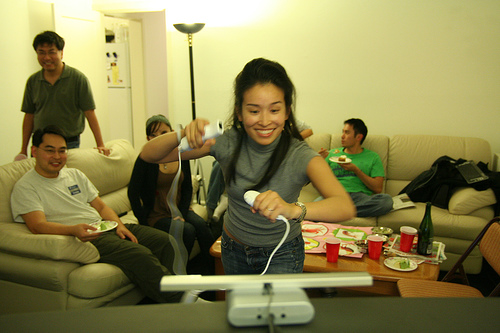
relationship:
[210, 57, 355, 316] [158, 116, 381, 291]
girl playing wii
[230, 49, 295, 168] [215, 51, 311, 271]
hair on girl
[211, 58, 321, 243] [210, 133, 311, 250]
woman wearing shirt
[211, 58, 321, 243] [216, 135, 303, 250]
woman wearing shirt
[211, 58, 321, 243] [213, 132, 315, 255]
woman wearing shirt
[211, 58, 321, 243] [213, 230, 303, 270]
woman wearing pants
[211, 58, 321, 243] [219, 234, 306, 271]
woman wearing pants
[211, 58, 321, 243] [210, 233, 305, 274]
woman wearing jeans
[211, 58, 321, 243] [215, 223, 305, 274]
woman wearing jeans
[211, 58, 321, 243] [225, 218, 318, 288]
woman wearing jeans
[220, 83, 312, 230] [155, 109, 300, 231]
woman holding remotes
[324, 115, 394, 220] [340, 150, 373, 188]
man wearing shirt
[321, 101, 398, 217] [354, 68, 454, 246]
man on couch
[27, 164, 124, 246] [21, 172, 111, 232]
man wearing shirt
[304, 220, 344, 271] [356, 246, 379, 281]
cup on table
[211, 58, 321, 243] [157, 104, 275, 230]
woman holding remotes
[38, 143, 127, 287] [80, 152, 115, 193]
man on sofa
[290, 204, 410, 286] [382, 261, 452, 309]
cups on table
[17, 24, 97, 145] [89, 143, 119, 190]
man behind sofa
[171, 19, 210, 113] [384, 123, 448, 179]
light behind sofa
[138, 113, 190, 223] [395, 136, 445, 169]
woman on sofa